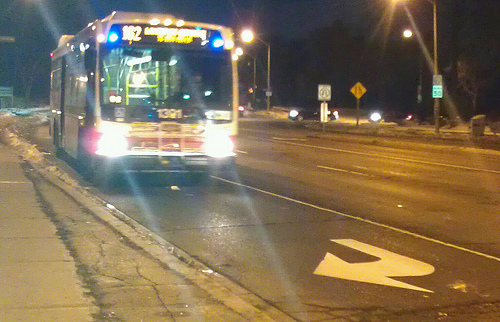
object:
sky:
[86, 1, 386, 38]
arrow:
[312, 235, 436, 296]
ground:
[1, 124, 499, 321]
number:
[120, 25, 145, 41]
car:
[287, 105, 340, 124]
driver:
[188, 71, 209, 107]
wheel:
[94, 163, 125, 194]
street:
[33, 122, 499, 321]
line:
[209, 174, 498, 263]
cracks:
[19, 134, 281, 321]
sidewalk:
[1, 141, 302, 322]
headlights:
[95, 129, 236, 161]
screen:
[119, 23, 210, 47]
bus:
[47, 8, 241, 183]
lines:
[210, 134, 499, 266]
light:
[240, 28, 255, 44]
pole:
[256, 36, 275, 112]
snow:
[0, 105, 80, 186]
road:
[33, 120, 500, 322]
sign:
[432, 84, 443, 100]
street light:
[239, 28, 272, 112]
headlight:
[289, 108, 299, 119]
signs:
[431, 73, 445, 100]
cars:
[287, 104, 416, 126]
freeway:
[279, 114, 499, 136]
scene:
[0, 0, 499, 321]